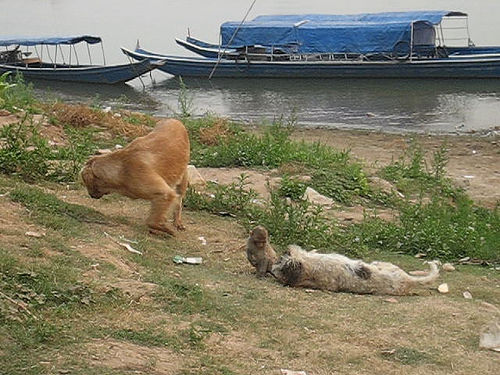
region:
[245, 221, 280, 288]
Monkey playing with dog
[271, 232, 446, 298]
Dog playing with monkey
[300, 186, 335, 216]
Large rock lying on the ground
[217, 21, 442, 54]
Cover on a boat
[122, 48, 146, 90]
Rope used for anchor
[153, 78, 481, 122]
Reflection of the boat in the water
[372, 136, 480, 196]
Weeds growing in the dirt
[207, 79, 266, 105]
Ripples in the water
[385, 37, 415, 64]
Old tire attached to boat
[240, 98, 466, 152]
Shoreline of large body of water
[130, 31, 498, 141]
blue boat on water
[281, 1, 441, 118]
blue boat on water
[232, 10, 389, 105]
blue boat on water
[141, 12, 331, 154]
blue boat on water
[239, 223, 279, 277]
a monkey petting a dog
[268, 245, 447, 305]
a white dog with black spots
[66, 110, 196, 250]
a big yellow dog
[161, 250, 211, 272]
a piece of trash on the ground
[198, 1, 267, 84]
large paddle for a fishing boat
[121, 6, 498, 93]
a large fishing boat in the water.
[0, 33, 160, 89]
a smaller fishing boat in the water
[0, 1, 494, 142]
a body of water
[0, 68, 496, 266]
patches of tall grass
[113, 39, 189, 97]
ropes holding the anchor in the water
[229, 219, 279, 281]
A monkey on the ground.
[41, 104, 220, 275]
A dog on the hill.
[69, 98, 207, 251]
The light brown dog.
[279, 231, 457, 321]
A dog laying down.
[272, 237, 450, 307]
A white patchy dog.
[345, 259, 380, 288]
A brown patch of fur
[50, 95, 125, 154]
Trash on the hill.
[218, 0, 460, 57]
Tarps on the boat.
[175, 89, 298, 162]
Weeds on the beach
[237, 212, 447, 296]
A dog and monkey play.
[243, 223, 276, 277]
small monkey crouched on ground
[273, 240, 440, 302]
fluffy dog laying down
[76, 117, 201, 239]
golden colored dog turning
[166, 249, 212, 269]
piece of litter on ground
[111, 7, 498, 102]
boat in the water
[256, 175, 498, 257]
plants growing in ground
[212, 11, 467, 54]
tarp covering boat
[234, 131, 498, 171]
sandy shore meets water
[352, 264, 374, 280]
spot on dog's back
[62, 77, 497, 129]
large body of water